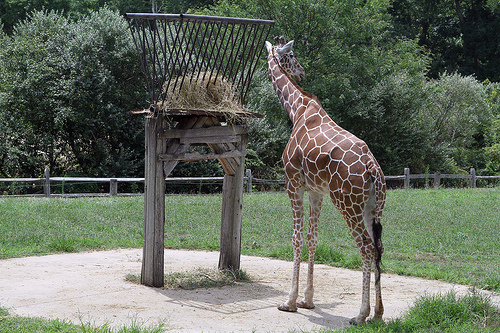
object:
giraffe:
[264, 39, 386, 326]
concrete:
[0, 247, 500, 332]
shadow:
[149, 275, 321, 315]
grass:
[403, 197, 498, 265]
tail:
[370, 164, 383, 283]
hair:
[372, 218, 382, 284]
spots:
[292, 133, 331, 168]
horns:
[274, 36, 287, 45]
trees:
[0, 7, 92, 177]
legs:
[355, 220, 385, 312]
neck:
[267, 65, 338, 124]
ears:
[282, 39, 295, 53]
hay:
[162, 71, 249, 136]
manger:
[152, 70, 250, 138]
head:
[265, 39, 306, 80]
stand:
[142, 117, 251, 288]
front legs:
[305, 190, 324, 297]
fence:
[1, 166, 498, 194]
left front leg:
[287, 183, 304, 299]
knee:
[306, 234, 319, 248]